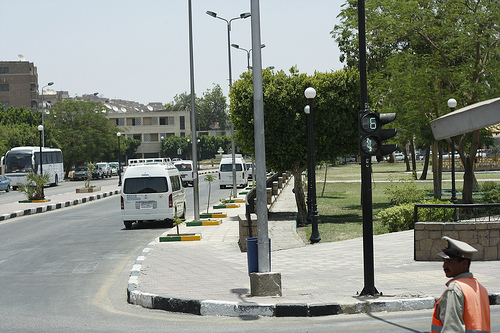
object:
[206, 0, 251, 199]
street lamp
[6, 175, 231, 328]
road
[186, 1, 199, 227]
street lamp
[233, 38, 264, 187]
street lamp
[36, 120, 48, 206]
street lamp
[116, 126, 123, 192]
street lamp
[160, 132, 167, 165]
street lamp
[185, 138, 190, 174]
street lamp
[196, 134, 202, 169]
street lamp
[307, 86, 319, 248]
street lamp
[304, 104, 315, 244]
street lamp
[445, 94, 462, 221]
street lamp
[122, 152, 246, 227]
vans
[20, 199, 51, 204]
planters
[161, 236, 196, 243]
planters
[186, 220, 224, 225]
planters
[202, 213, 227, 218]
planters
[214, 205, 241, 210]
planters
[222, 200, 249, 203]
planters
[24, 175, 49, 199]
trees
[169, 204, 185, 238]
trees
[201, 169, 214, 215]
trees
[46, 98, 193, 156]
office building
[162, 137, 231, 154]
bushes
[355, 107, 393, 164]
crosswalk light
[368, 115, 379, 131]
number 6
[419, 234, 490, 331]
crossing guard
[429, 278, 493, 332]
vest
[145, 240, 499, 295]
sidewalk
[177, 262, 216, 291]
bricks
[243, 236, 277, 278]
trash bin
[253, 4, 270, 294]
street lamp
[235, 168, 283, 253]
fence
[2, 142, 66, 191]
bus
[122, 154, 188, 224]
van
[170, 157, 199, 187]
van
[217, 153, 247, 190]
van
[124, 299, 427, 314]
street curb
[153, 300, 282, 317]
stripes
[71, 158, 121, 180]
cars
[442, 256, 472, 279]
head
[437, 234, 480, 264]
hat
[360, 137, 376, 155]
electric pedestrian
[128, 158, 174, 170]
raised roof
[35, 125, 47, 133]
globe lights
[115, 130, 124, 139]
globe lights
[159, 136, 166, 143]
globe lights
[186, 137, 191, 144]
globe lights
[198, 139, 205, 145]
globe lights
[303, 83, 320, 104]
globe lights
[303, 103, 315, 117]
globe lights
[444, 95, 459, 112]
globe lights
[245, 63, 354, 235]
sapling tree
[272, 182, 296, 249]
walkway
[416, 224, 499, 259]
wall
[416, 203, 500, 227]
rail